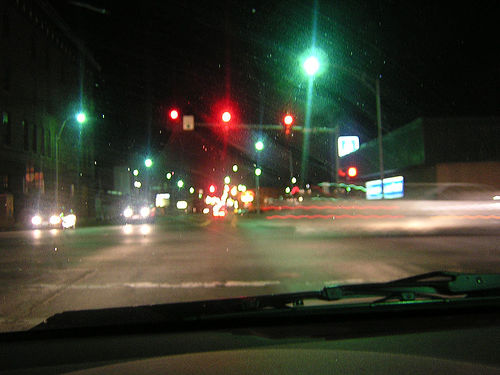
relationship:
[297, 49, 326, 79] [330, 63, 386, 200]
light on pole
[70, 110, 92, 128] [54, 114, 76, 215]
light on pole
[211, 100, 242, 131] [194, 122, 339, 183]
light on pole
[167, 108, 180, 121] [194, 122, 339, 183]
light on pole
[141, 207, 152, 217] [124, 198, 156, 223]
light on car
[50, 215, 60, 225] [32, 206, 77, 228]
light on car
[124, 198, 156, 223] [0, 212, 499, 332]
car on street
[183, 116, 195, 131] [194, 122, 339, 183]
sign on pole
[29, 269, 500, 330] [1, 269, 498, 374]
windshield wiper on car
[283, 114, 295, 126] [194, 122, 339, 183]
light on pole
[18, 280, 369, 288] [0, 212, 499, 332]
line on street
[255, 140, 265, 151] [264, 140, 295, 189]
light on pole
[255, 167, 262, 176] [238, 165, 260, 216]
light on pole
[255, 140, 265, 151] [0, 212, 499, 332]
light on side of street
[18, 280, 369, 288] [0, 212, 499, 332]
line painted on street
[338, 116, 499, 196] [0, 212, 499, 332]
building on side of street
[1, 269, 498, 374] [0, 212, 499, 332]
car moving on street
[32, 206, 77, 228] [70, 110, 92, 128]
car under light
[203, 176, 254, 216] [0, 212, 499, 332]
lights on street